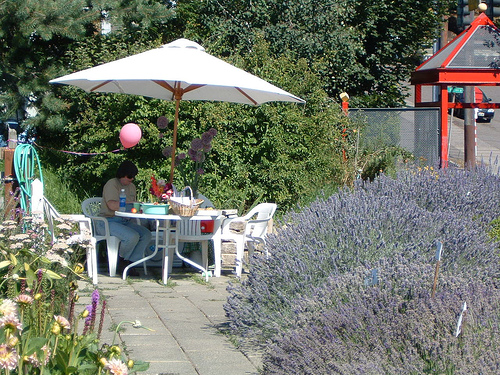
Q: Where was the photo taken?
A: It was taken at the patio.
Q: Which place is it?
A: It is a patio.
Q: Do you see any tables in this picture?
A: Yes, there is a table.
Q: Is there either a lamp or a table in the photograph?
A: Yes, there is a table.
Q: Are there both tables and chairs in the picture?
A: Yes, there are both a table and a chair.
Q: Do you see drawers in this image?
A: No, there are no drawers.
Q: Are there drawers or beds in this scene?
A: No, there are no drawers or beds.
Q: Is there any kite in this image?
A: No, there are no kites.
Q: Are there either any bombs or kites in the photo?
A: No, there are no kites or bombs.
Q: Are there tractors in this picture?
A: No, there are no tractors.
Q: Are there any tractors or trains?
A: No, there are no tractors or trains.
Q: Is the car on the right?
A: Yes, the car is on the right of the image.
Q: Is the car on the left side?
A: No, the car is on the right of the image.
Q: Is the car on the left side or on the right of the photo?
A: The car is on the right of the image.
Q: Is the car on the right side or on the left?
A: The car is on the right of the image.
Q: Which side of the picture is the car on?
A: The car is on the right of the image.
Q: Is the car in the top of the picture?
A: Yes, the car is in the top of the image.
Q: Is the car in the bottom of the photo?
A: No, the car is in the top of the image.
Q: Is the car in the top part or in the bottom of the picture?
A: The car is in the top of the image.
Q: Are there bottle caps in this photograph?
A: No, there are no bottle caps.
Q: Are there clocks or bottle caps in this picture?
A: No, there are no bottle caps or clocks.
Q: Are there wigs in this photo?
A: No, there are no wigs.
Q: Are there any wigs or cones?
A: No, there are no wigs or cones.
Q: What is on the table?
A: The basket is on the table.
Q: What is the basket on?
A: The basket is on the table.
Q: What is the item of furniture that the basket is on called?
A: The piece of furniture is a table.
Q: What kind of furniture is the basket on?
A: The basket is on the table.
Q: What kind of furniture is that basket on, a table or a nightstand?
A: The basket is on a table.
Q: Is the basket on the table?
A: Yes, the basket is on the table.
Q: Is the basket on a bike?
A: No, the basket is on the table.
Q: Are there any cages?
A: No, there are no cages.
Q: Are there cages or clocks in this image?
A: No, there are no cages or clocks.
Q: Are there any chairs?
A: Yes, there is a chair.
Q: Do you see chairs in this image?
A: Yes, there is a chair.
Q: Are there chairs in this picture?
A: Yes, there is a chair.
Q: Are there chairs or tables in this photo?
A: Yes, there is a chair.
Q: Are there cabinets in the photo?
A: No, there are no cabinets.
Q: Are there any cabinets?
A: No, there are no cabinets.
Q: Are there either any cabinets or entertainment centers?
A: No, there are no cabinets or entertainment centers.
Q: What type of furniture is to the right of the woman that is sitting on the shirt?
A: The piece of furniture is a chair.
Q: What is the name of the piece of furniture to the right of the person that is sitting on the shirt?
A: The piece of furniture is a chair.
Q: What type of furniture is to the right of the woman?
A: The piece of furniture is a chair.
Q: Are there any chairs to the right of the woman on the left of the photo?
A: Yes, there is a chair to the right of the woman.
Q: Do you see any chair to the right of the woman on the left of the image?
A: Yes, there is a chair to the right of the woman.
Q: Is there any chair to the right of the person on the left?
A: Yes, there is a chair to the right of the woman.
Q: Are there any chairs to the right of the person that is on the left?
A: Yes, there is a chair to the right of the woman.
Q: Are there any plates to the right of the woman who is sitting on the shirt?
A: No, there is a chair to the right of the woman.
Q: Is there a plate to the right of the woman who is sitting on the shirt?
A: No, there is a chair to the right of the woman.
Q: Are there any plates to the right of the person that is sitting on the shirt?
A: No, there is a chair to the right of the woman.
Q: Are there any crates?
A: No, there are no crates.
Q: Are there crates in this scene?
A: No, there are no crates.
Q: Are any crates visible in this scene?
A: No, there are no crates.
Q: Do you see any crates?
A: No, there are no crates.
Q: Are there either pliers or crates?
A: No, there are no crates or pliers.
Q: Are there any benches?
A: No, there are no benches.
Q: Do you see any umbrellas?
A: Yes, there is an umbrella.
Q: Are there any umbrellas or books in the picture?
A: Yes, there is an umbrella.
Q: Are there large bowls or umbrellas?
A: Yes, there is a large umbrella.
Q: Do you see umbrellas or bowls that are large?
A: Yes, the umbrella is large.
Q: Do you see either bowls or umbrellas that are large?
A: Yes, the umbrella is large.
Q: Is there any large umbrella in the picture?
A: Yes, there is a large umbrella.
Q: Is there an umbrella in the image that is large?
A: Yes, there is an umbrella that is large.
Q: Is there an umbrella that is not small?
A: Yes, there is a large umbrella.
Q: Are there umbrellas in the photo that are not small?
A: Yes, there is a large umbrella.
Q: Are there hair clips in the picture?
A: No, there are no hair clips.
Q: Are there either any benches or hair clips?
A: No, there are no hair clips or benches.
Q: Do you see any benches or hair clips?
A: No, there are no hair clips or benches.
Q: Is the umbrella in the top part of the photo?
A: Yes, the umbrella is in the top of the image.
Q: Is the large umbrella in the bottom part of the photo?
A: No, the umbrella is in the top of the image.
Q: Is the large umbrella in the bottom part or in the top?
A: The umbrella is in the top of the image.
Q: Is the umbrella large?
A: Yes, the umbrella is large.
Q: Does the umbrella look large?
A: Yes, the umbrella is large.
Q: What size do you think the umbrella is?
A: The umbrella is large.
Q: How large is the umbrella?
A: The umbrella is large.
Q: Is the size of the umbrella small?
A: No, the umbrella is large.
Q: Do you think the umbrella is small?
A: No, the umbrella is large.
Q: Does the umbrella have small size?
A: No, the umbrella is large.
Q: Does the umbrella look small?
A: No, the umbrella is large.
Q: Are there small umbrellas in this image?
A: No, there is an umbrella but it is large.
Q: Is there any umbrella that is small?
A: No, there is an umbrella but it is large.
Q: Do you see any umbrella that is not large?
A: No, there is an umbrella but it is large.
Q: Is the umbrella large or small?
A: The umbrella is large.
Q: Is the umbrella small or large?
A: The umbrella is large.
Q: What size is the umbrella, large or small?
A: The umbrella is large.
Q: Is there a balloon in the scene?
A: Yes, there is a balloon.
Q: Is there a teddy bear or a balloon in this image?
A: Yes, there is a balloon.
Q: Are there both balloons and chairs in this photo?
A: Yes, there are both a balloon and a chair.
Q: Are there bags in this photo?
A: No, there are no bags.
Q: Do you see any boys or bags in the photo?
A: No, there are no bags or boys.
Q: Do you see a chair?
A: Yes, there is a chair.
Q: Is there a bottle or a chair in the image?
A: Yes, there is a chair.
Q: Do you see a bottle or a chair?
A: Yes, there is a chair.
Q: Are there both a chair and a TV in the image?
A: No, there is a chair but no televisions.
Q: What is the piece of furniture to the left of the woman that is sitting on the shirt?
A: The piece of furniture is a chair.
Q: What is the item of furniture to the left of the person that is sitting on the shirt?
A: The piece of furniture is a chair.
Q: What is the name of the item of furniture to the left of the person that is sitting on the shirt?
A: The piece of furniture is a chair.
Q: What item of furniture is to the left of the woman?
A: The piece of furniture is a chair.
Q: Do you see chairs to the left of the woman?
A: Yes, there is a chair to the left of the woman.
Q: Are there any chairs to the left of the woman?
A: Yes, there is a chair to the left of the woman.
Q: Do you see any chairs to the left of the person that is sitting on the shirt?
A: Yes, there is a chair to the left of the woman.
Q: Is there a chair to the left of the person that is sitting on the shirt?
A: Yes, there is a chair to the left of the woman.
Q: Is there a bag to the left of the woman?
A: No, there is a chair to the left of the woman.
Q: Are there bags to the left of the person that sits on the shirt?
A: No, there is a chair to the left of the woman.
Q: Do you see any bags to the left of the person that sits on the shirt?
A: No, there is a chair to the left of the woman.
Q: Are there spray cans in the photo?
A: No, there are no spray cans.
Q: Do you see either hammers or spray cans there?
A: No, there are no spray cans or hammers.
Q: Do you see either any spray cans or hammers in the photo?
A: No, there are no spray cans or hammers.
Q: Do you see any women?
A: Yes, there is a woman.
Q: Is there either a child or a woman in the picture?
A: Yes, there is a woman.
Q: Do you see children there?
A: No, there are no children.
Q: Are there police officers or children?
A: No, there are no children or police officers.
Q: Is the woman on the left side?
A: Yes, the woman is on the left of the image.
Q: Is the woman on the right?
A: No, the woman is on the left of the image.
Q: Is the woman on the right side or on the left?
A: The woman is on the left of the image.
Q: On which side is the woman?
A: The woman is on the left of the image.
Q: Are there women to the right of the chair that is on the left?
A: Yes, there is a woman to the right of the chair.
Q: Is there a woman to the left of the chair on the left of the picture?
A: No, the woman is to the right of the chair.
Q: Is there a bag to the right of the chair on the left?
A: No, there is a woman to the right of the chair.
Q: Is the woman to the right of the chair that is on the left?
A: Yes, the woman is to the right of the chair.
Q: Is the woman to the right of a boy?
A: No, the woman is to the right of the chair.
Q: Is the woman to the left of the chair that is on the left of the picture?
A: No, the woman is to the right of the chair.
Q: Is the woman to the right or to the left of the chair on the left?
A: The woman is to the right of the chair.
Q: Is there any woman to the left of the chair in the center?
A: Yes, there is a woman to the left of the chair.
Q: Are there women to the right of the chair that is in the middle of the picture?
A: No, the woman is to the left of the chair.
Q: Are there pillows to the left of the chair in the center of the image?
A: No, there is a woman to the left of the chair.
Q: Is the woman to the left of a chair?
A: Yes, the woman is to the left of a chair.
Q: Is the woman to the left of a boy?
A: No, the woman is to the left of a chair.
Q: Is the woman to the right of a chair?
A: No, the woman is to the left of a chair.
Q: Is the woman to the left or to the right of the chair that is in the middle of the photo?
A: The woman is to the left of the chair.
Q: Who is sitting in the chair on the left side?
A: The woman is sitting in the chair.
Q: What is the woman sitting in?
A: The woman is sitting in the chair.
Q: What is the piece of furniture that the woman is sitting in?
A: The piece of furniture is a chair.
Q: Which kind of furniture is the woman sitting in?
A: The woman is sitting in the chair.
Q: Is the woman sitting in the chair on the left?
A: Yes, the woman is sitting in the chair.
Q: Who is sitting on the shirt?
A: The woman is sitting on the shirt.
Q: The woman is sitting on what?
A: The woman is sitting on the shirt.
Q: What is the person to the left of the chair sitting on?
A: The woman is sitting on the shirt.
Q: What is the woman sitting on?
A: The woman is sitting on the shirt.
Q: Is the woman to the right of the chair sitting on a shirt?
A: Yes, the woman is sitting on a shirt.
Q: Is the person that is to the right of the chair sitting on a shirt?
A: Yes, the woman is sitting on a shirt.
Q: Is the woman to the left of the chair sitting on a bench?
A: No, the woman is sitting on a shirt.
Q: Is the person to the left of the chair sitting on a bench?
A: No, the woman is sitting on a shirt.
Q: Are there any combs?
A: No, there are no combs.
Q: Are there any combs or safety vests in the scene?
A: No, there are no combs or safety vests.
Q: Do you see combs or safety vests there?
A: No, there are no combs or safety vests.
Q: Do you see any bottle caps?
A: No, there are no bottle caps.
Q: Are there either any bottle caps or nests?
A: No, there are no bottle caps or nests.